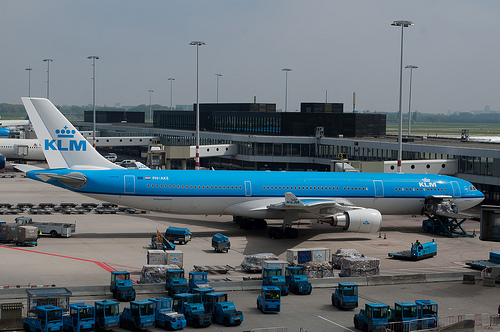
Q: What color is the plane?
A: Blue and white.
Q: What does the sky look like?
A: Overcast.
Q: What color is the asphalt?
A: Grey.